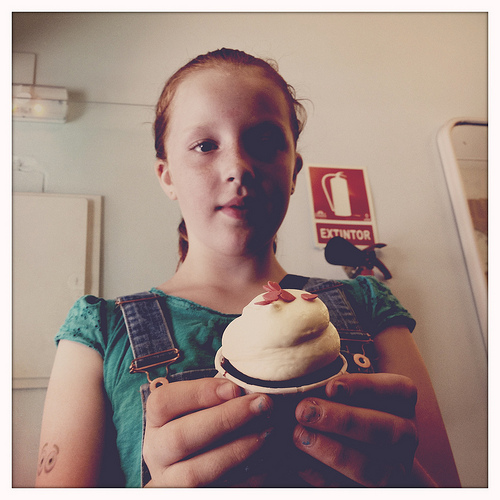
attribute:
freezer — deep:
[13, 192, 105, 489]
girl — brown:
[69, 55, 497, 465]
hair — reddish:
[135, 44, 354, 124]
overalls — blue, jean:
[310, 275, 366, 377]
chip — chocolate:
[300, 289, 317, 300]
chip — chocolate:
[278, 287, 294, 303]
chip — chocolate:
[265, 279, 282, 291]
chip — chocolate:
[262, 292, 281, 304]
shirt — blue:
[55, 273, 450, 491]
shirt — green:
[56, 275, 416, 490]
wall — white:
[0, 47, 487, 466]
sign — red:
[297, 161, 390, 249]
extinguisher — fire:
[322, 236, 397, 282]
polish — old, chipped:
[218, 394, 359, 459]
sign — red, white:
[283, 162, 437, 269]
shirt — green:
[89, 269, 456, 387]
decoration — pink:
[300, 289, 319, 303]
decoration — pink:
[277, 289, 295, 303]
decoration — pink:
[254, 298, 275, 307]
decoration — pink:
[262, 291, 279, 302]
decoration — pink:
[266, 279, 281, 291]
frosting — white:
[215, 280, 342, 375]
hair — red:
[139, 32, 305, 272]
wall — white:
[15, 13, 493, 499]